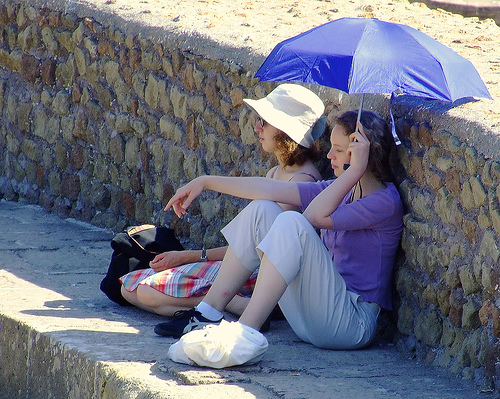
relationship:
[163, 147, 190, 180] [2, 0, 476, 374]
brick on wall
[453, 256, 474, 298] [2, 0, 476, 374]
brick on wall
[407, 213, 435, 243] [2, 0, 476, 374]
brick on wall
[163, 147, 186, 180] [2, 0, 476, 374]
brick on wall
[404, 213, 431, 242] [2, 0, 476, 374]
brick on wall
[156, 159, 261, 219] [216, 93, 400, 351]
hand of woman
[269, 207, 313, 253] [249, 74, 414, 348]
knee of woman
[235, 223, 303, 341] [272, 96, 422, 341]
leg of woman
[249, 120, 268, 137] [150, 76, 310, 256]
nose of woman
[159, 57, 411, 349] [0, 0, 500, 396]
two girls sitting by a wall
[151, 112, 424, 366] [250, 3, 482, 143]
girl holding an umbrella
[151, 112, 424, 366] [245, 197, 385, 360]
girl wearing tan pants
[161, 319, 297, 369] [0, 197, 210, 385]
package on sidewalk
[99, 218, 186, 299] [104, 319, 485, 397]
back pack on sidewalk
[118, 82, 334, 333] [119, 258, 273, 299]
woman wearing a skirt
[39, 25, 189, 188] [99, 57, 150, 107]
wall made of many stones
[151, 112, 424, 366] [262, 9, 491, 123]
girl holding umbrella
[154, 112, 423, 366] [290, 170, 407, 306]
girl wearing shirt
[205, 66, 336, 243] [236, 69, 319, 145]
woman with hat